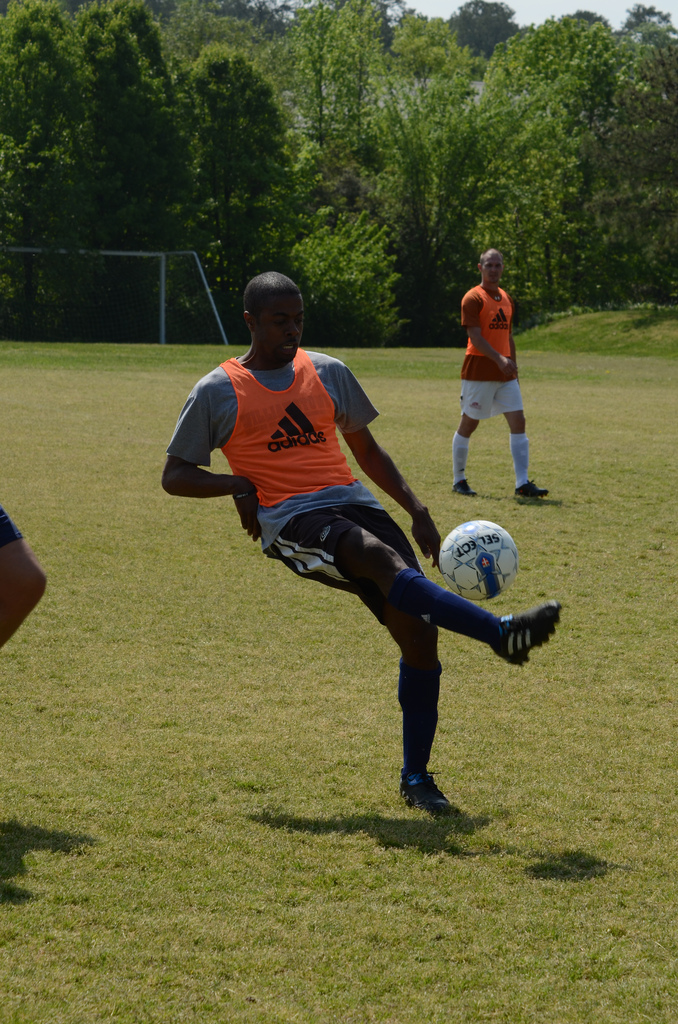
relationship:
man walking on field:
[419, 236, 596, 517] [33, 236, 596, 855]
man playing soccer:
[213, 288, 561, 765] [19, 13, 677, 1021]